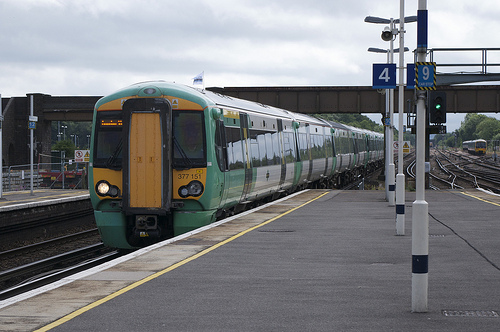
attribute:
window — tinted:
[173, 110, 204, 165]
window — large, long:
[250, 130, 280, 165]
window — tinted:
[95, 116, 123, 166]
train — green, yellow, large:
[86, 81, 385, 250]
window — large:
[311, 134, 326, 158]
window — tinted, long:
[333, 136, 349, 154]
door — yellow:
[129, 111, 162, 207]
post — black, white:
[411, 0, 428, 313]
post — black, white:
[396, 0, 405, 235]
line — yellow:
[28, 190, 333, 331]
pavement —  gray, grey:
[0, 188, 500, 331]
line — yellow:
[459, 191, 499, 209]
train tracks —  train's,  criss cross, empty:
[394, 148, 500, 189]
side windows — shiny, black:
[212, 125, 384, 173]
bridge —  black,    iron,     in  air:
[0, 86, 499, 172]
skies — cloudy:
[0, 0, 500, 98]